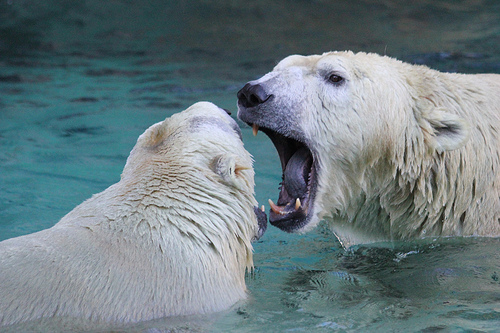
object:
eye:
[323, 70, 349, 87]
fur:
[374, 52, 498, 243]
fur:
[140, 139, 264, 298]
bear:
[235, 49, 499, 249]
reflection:
[285, 247, 412, 322]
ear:
[415, 97, 467, 151]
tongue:
[279, 143, 317, 201]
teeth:
[294, 196, 301, 208]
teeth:
[267, 198, 285, 214]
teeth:
[251, 124, 260, 137]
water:
[306, 246, 497, 331]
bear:
[3, 100, 267, 326]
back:
[49, 199, 167, 268]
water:
[79, 62, 150, 120]